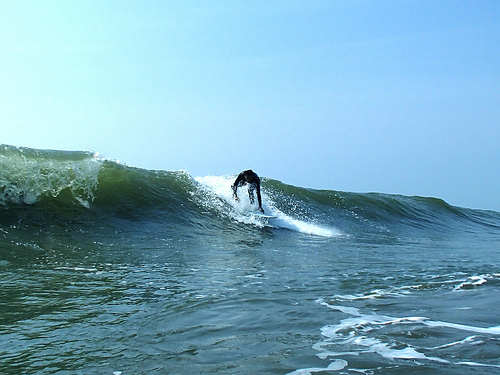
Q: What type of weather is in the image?
A: It is cloudless.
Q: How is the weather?
A: It is cloudless.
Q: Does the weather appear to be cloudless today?
A: Yes, it is cloudless.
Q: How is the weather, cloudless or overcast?
A: It is cloudless.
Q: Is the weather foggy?
A: No, it is cloudless.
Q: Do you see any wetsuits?
A: Yes, there is a wetsuit.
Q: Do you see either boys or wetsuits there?
A: Yes, there is a wetsuit.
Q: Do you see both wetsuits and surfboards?
A: Yes, there are both a wetsuit and a surfboard.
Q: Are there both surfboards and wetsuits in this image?
A: Yes, there are both a wetsuit and a surfboard.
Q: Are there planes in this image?
A: No, there are no planes.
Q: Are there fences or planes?
A: No, there are no planes or fences.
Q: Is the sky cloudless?
A: Yes, the sky is cloudless.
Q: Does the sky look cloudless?
A: Yes, the sky is cloudless.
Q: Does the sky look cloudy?
A: No, the sky is cloudless.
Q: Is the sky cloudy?
A: No, the sky is cloudless.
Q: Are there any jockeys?
A: No, there are no jockeys.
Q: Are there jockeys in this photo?
A: No, there are no jockeys.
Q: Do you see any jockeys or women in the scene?
A: No, there are no jockeys or women.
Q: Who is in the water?
A: The man is in the water.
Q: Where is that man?
A: The man is in the water.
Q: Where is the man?
A: The man is in the water.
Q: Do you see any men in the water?
A: Yes, there is a man in the water.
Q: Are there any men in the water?
A: Yes, there is a man in the water.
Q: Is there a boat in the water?
A: No, there is a man in the water.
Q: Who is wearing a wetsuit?
A: The man is wearing a wetsuit.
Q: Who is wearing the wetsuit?
A: The man is wearing a wetsuit.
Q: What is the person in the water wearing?
A: The man is wearing a wetsuit.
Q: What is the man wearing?
A: The man is wearing a wetsuit.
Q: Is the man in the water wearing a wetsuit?
A: Yes, the man is wearing a wetsuit.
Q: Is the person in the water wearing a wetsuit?
A: Yes, the man is wearing a wetsuit.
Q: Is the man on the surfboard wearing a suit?
A: No, the man is wearing a wetsuit.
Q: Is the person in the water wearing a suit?
A: No, the man is wearing a wetsuit.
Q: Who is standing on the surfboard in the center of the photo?
A: The man is standing on the surfboard.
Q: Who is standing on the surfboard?
A: The man is standing on the surfboard.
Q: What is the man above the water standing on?
A: The man is standing on the surfboard.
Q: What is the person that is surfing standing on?
A: The man is standing on the surfboard.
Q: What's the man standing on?
A: The man is standing on the surfboard.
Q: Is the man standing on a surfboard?
A: Yes, the man is standing on a surfboard.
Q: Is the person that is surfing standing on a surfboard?
A: Yes, the man is standing on a surfboard.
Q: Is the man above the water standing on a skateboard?
A: No, the man is standing on a surfboard.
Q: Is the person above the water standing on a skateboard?
A: No, the man is standing on a surfboard.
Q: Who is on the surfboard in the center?
A: The man is on the surfboard.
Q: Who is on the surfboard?
A: The man is on the surfboard.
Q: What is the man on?
A: The man is on the surfboard.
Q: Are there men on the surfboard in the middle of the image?
A: Yes, there is a man on the surfboard.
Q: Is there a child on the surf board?
A: No, there is a man on the surf board.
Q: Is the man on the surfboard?
A: Yes, the man is on the surfboard.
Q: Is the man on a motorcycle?
A: No, the man is on the surfboard.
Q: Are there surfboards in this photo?
A: Yes, there is a surfboard.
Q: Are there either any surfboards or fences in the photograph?
A: Yes, there is a surfboard.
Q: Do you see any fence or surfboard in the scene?
A: Yes, there is a surfboard.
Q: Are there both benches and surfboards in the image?
A: No, there is a surfboard but no benches.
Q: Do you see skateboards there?
A: No, there are no skateboards.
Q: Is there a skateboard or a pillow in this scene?
A: No, there are no skateboards or pillows.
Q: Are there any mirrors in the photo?
A: No, there are no mirrors.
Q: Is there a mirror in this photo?
A: No, there are no mirrors.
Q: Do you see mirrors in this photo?
A: No, there are no mirrors.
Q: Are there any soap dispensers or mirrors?
A: No, there are no mirrors or soap dispensers.